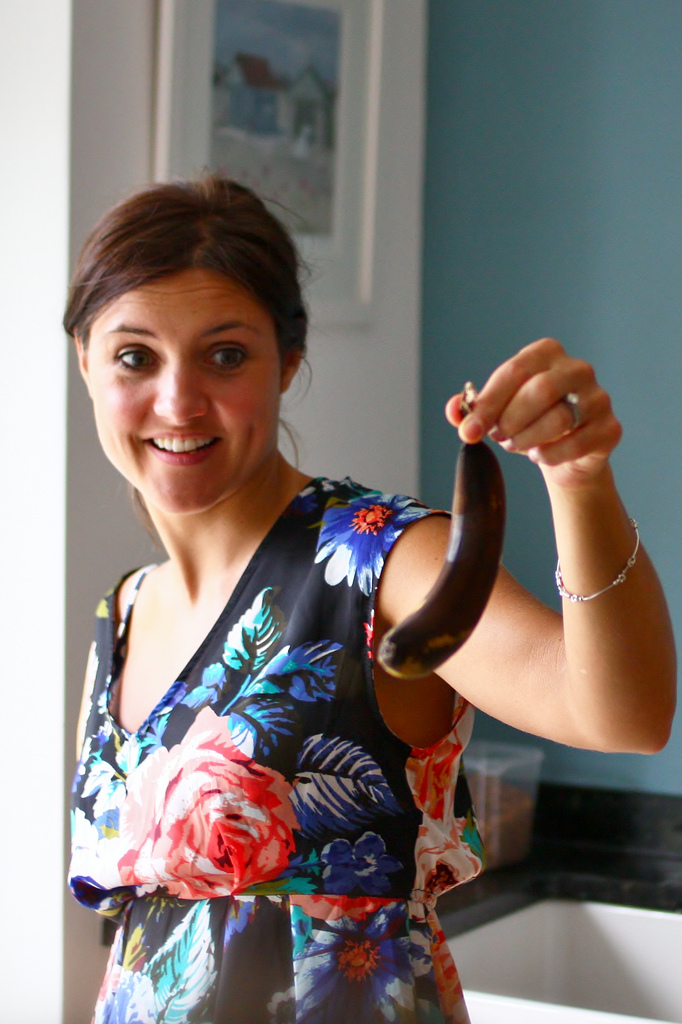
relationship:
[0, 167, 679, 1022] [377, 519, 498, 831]
she holding a banana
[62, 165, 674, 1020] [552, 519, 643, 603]
she wearing a bracelet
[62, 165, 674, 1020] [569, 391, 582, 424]
she wearing a ring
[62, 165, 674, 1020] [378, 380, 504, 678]
she very surpred by banana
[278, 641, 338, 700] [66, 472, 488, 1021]
blue on dress